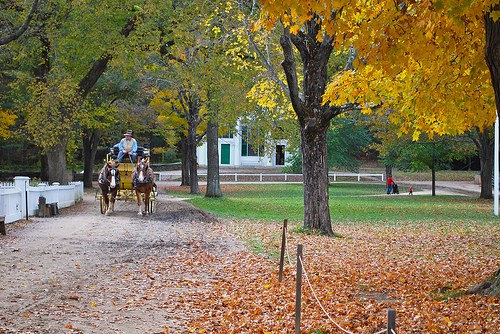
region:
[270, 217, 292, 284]
a wooden post on a fence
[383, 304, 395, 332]
a wooden post on a fence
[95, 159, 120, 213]
a horse pulling a carriage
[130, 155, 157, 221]
a horse pulling a carriage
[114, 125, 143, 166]
a man driving a carriage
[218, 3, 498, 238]
a tree with yellow leaves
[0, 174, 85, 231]
a white fence near the street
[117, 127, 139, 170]
a man in a beige vest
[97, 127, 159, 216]
A horse drawn carriage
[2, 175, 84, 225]
A white picket fence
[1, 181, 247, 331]
A dirt path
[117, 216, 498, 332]
Fallen leaves on the ground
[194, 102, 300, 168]
A white house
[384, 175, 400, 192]
A person pushing a stroller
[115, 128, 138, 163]
A man driving a carriage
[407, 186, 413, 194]
A child wearing red and black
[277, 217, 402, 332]
A wooden fence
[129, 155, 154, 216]
A brown and white horse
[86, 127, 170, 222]
Two horses pulling carriage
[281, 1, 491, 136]
Yellow leaves on tree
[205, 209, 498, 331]
Colorful leaves on the ground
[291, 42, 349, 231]
Old tree trunk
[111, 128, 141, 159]
Man with vest driving carriage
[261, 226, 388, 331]
Decorative rope fence along trail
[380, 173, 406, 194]
Person pushing black stroller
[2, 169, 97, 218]
White picket fence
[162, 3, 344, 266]
Row of trees on side of trail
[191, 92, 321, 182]
House behind trail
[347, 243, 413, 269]
the leaves on the grass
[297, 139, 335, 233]
a tree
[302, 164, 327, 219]
the bark on the tree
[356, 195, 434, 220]
a field of green grass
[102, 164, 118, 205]
a tall horse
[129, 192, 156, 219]
the horses legs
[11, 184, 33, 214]
a white fence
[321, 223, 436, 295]
leaves covering the ground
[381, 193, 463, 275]
leaves covering the grass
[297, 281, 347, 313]
silver chain for fence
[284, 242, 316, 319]
black fence pole in ground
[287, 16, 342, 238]
large brown trunk of tree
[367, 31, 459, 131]
yellow and green leaves on tree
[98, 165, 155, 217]
two horses carrying carriage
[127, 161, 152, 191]
white top of horse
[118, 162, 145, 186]
yellow wooden carraige being pulled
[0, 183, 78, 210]
white picket fence by road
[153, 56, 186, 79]
green leaves on the tree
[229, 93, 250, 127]
green leaves on the tree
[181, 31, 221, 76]
green leaves on the tree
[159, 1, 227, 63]
green leaves on the tree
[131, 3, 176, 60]
green leaves on the tree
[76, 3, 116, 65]
green leaves on the tree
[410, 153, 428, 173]
green leaves on the tree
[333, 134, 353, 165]
green leaves on the tree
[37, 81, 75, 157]
green leaves on the tree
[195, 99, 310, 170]
white building with green trim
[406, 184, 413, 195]
young child wearing red shirt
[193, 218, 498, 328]
brown and orange leaves covering the grass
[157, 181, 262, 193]
brown and orange leaves covering the grass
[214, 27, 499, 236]
large tree with red and yellow leaves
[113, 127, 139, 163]
carriage driver wearing blue shirt and white vest